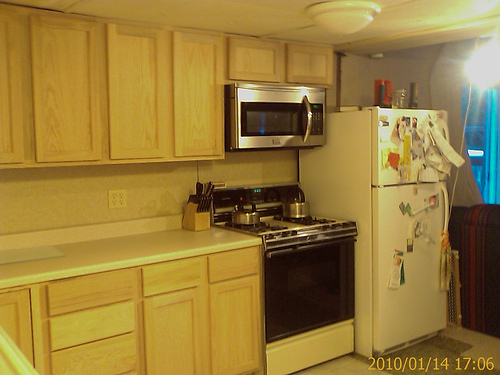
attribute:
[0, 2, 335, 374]
cabinets — wooden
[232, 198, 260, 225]
tea kettle — metal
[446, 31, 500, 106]
light — hanging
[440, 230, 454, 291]
hand towel — hanging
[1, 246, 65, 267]
cutting board — glass